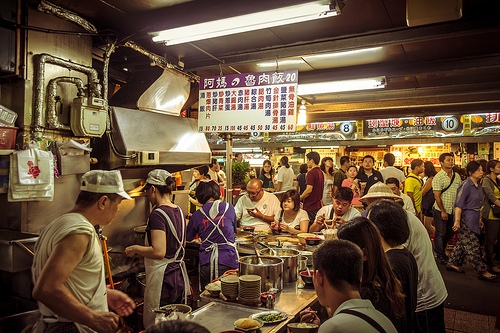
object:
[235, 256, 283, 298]
pot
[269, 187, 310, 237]
woman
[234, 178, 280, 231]
man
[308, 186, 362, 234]
man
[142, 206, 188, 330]
apron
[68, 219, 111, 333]
apron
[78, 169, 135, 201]
hat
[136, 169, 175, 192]
hat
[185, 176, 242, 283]
woman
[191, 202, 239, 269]
purple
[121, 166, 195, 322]
worker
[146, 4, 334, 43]
light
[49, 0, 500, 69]
ceiling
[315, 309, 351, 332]
shoulder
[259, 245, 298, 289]
pot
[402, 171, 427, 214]
shirt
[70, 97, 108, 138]
gas meter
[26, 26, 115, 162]
wall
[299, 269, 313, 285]
bowl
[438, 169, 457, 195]
strap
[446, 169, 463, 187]
shoulder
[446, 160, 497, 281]
people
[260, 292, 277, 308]
cup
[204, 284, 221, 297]
cap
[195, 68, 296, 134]
sign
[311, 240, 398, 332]
people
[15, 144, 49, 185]
bags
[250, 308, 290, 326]
plate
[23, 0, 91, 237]
oven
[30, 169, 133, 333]
man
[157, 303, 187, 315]
food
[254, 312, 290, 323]
food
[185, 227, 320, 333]
counter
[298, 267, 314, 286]
soup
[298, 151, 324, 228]
man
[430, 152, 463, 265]
man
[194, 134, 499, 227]
market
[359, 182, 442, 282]
man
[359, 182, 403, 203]
hat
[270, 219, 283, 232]
food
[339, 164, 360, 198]
woman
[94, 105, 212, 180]
hood fan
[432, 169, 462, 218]
shirt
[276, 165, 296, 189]
shirt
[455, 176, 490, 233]
shirt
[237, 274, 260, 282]
dishes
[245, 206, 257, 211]
food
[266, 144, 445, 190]
line